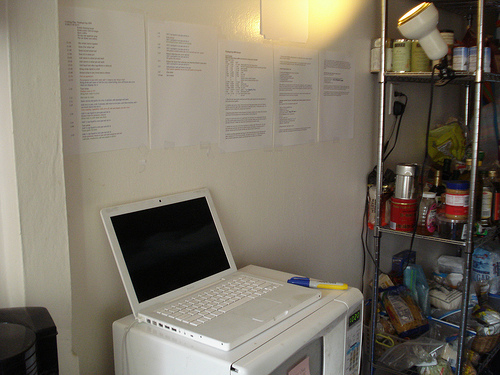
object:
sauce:
[416, 220, 436, 236]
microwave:
[105, 264, 371, 374]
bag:
[376, 281, 432, 338]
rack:
[359, 0, 500, 375]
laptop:
[98, 187, 325, 353]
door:
[230, 313, 347, 375]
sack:
[469, 248, 499, 301]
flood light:
[393, 2, 451, 63]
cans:
[451, 43, 471, 73]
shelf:
[382, 66, 499, 83]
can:
[388, 194, 417, 233]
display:
[346, 309, 363, 327]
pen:
[286, 274, 349, 291]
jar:
[442, 177, 470, 220]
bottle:
[415, 189, 439, 237]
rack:
[371, 219, 499, 247]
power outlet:
[385, 83, 409, 117]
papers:
[56, 0, 148, 159]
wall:
[2, 1, 454, 371]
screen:
[110, 196, 230, 304]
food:
[441, 176, 470, 218]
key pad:
[153, 273, 281, 328]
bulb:
[395, 3, 428, 24]